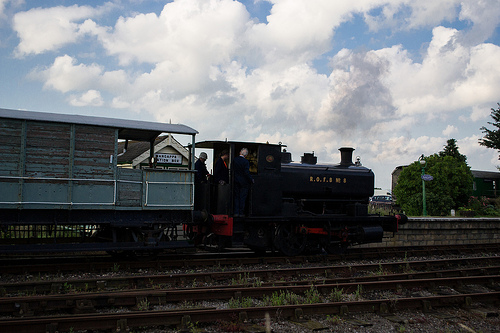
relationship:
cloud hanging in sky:
[325, 44, 396, 120] [1, 0, 483, 192]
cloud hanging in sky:
[9, 2, 111, 59] [1, 0, 483, 192]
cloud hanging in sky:
[10, 3, 104, 56] [1, 0, 483, 192]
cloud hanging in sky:
[64, 87, 104, 109] [1, 0, 483, 192]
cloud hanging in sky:
[79, 1, 257, 91] [1, 0, 483, 192]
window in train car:
[118, 126, 190, 177] [10, 111, 196, 249]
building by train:
[105, 125, 179, 182] [105, 123, 389, 292]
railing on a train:
[0, 174, 200, 206] [1, 105, 384, 265]